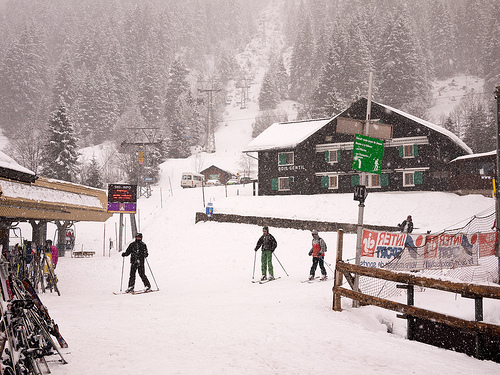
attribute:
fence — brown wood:
[332, 288, 494, 327]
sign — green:
[349, 127, 391, 172]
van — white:
[176, 169, 205, 190]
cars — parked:
[178, 170, 259, 188]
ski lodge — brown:
[236, 95, 484, 195]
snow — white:
[84, 291, 360, 372]